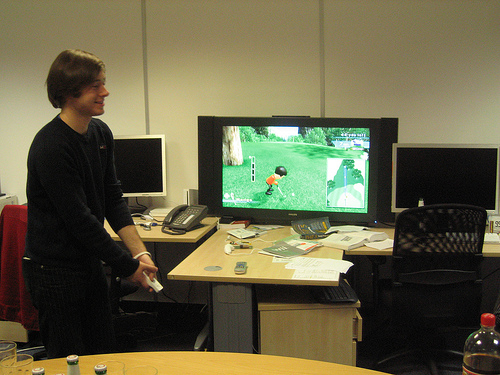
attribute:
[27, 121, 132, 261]
shirt — black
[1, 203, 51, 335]
jacket — red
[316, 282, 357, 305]
keyboard — black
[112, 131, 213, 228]
monitor — computer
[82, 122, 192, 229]
monitor — black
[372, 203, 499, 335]
computer chair — black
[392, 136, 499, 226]
monitor — computer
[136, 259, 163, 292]
controller — white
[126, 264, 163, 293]
controller — white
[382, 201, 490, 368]
chair — black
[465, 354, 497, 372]
soda — half-empty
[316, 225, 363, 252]
book — open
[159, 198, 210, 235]
telephone — black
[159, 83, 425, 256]
tv — black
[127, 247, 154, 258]
band — white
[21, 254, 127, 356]
pants — black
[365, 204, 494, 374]
chair — empty